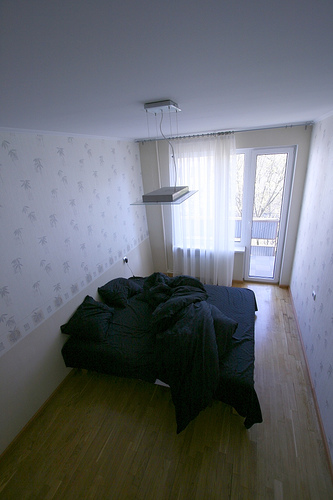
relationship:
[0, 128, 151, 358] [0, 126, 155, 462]
wallpaper on wall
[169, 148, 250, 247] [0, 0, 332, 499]
window in bedroom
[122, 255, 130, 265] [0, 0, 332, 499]
outlet in bedroom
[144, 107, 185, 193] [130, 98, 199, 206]
wires from light fixture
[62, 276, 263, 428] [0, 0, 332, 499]
bed in bedroom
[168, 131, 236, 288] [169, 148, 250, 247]
curtain over window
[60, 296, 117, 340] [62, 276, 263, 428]
pillow on bed